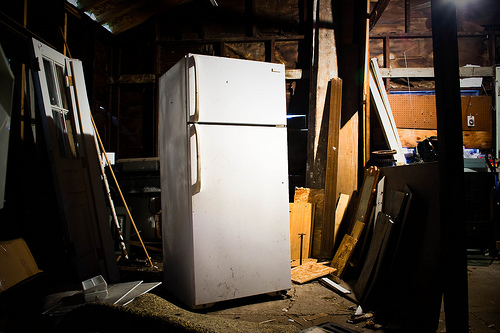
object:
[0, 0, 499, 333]
building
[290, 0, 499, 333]
work area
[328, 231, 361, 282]
pieces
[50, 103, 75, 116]
stick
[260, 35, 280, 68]
post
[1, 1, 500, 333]
room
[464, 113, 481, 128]
meter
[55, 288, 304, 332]
pad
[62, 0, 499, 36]
ceiling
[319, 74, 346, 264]
building materials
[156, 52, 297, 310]
freezer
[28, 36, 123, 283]
door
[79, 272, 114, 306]
ice makers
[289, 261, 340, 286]
fiberboard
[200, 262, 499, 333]
floor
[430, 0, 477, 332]
column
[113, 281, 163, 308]
boards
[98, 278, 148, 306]
shelves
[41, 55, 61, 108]
window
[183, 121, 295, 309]
door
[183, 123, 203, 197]
handle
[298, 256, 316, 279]
plywood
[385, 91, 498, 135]
cork board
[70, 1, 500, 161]
wall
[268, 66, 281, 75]
logo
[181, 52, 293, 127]
door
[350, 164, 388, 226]
framed mirror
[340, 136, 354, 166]
plywood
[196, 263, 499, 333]
ground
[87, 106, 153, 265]
handle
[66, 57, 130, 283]
mop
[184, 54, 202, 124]
handle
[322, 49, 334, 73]
wood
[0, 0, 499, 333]
garage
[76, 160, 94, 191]
wood